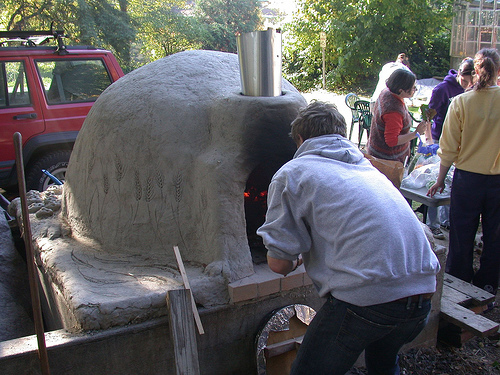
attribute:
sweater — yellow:
[431, 79, 483, 183]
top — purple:
[419, 65, 465, 142]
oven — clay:
[52, 7, 322, 277]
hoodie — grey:
[262, 136, 437, 306]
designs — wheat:
[73, 144, 176, 295]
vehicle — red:
[3, 27, 129, 203]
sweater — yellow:
[437, 83, 484, 177]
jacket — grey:
[268, 136, 442, 299]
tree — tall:
[189, 2, 264, 50]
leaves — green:
[443, 7, 456, 17]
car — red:
[2, 22, 123, 184]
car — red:
[3, 25, 134, 184]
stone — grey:
[75, 47, 327, 257]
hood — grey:
[292, 134, 370, 165]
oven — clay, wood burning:
[68, 29, 307, 259]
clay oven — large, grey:
[63, 22, 296, 270]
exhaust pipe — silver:
[229, 29, 296, 95]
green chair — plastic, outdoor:
[355, 96, 378, 128]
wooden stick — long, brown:
[7, 134, 58, 374]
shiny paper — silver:
[253, 305, 319, 374]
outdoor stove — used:
[34, 23, 334, 275]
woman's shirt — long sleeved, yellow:
[423, 44, 500, 278]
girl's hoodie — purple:
[426, 59, 450, 146]